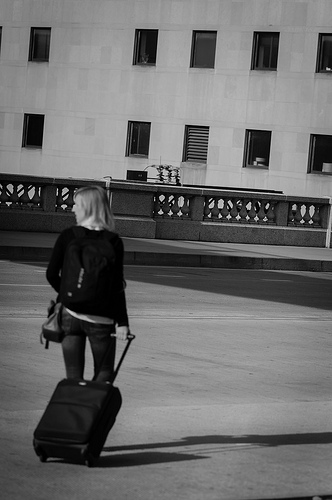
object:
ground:
[249, 313, 316, 353]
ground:
[267, 111, 287, 137]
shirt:
[58, 306, 116, 324]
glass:
[194, 32, 213, 67]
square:
[188, 28, 217, 69]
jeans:
[58, 302, 116, 385]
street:
[2, 261, 330, 446]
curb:
[2, 246, 331, 273]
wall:
[68, 44, 115, 144]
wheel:
[82, 460, 91, 467]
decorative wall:
[0, 168, 331, 247]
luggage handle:
[110, 332, 135, 339]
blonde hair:
[72, 186, 115, 230]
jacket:
[46, 225, 130, 329]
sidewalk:
[4, 233, 327, 269]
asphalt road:
[4, 258, 330, 497]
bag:
[39, 291, 65, 350]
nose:
[71, 204, 77, 213]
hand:
[114, 325, 131, 342]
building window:
[189, 29, 217, 71]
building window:
[26, 23, 51, 64]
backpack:
[56, 224, 122, 322]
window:
[242, 128, 275, 170]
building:
[1, 0, 330, 220]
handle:
[88, 330, 134, 383]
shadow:
[89, 432, 332, 467]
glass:
[310, 133, 321, 169]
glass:
[243, 130, 270, 169]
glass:
[129, 122, 150, 158]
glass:
[21, 112, 43, 150]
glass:
[26, 26, 50, 61]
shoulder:
[55, 225, 84, 254]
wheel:
[38, 451, 46, 462]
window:
[254, 32, 277, 70]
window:
[128, 122, 151, 157]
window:
[21, 112, 42, 148]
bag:
[32, 329, 135, 466]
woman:
[44, 186, 131, 387]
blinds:
[250, 31, 281, 72]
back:
[62, 226, 124, 326]